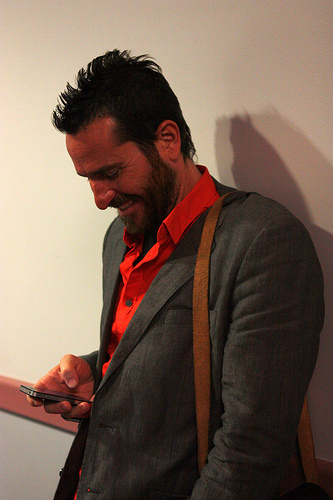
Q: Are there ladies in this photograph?
A: No, there are no ladies.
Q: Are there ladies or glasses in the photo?
A: No, there are no ladies or glasses.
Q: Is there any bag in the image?
A: Yes, there is a bag.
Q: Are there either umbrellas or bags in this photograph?
A: Yes, there is a bag.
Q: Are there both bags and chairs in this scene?
A: No, there is a bag but no chairs.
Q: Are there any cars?
A: No, there are no cars.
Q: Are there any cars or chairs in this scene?
A: No, there are no cars or chairs.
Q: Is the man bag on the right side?
A: Yes, the bag is on the right of the image.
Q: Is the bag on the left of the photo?
A: No, the bag is on the right of the image.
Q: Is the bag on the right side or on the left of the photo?
A: The bag is on the right of the image.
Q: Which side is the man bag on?
A: The bag is on the right of the image.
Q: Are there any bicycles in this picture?
A: No, there are no bicycles.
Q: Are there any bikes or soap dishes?
A: No, there are no bikes or soap dishes.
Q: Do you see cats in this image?
A: No, there are no cats.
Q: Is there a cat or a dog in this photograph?
A: No, there are no cats or dogs.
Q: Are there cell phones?
A: Yes, there is a cell phone.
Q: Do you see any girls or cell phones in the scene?
A: Yes, there is a cell phone.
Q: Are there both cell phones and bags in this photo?
A: Yes, there are both a cell phone and a bag.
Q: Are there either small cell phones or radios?
A: Yes, there is a small cell phone.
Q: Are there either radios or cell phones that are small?
A: Yes, the cell phone is small.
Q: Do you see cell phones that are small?
A: Yes, there is a small cell phone.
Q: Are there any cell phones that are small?
A: Yes, there is a cell phone that is small.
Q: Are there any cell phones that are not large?
A: Yes, there is a small cell phone.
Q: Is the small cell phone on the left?
A: Yes, the mobile phone is on the left of the image.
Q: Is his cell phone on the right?
A: No, the mobile phone is on the left of the image.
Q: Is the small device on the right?
A: No, the mobile phone is on the left of the image.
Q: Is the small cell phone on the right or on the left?
A: The mobile phone is on the left of the image.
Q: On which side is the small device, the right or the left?
A: The mobile phone is on the left of the image.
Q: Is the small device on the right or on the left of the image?
A: The mobile phone is on the left of the image.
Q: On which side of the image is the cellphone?
A: The cellphone is on the left of the image.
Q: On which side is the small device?
A: The cellphone is on the left of the image.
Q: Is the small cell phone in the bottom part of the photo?
A: Yes, the cellphone is in the bottom of the image.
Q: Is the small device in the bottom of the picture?
A: Yes, the cellphone is in the bottom of the image.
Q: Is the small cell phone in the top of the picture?
A: No, the cell phone is in the bottom of the image.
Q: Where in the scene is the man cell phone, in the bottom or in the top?
A: The cellphone is in the bottom of the image.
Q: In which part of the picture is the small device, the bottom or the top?
A: The cellphone is in the bottom of the image.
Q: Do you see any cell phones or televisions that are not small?
A: No, there is a cell phone but it is small.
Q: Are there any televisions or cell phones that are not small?
A: No, there is a cell phone but it is small.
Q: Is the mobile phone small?
A: Yes, the mobile phone is small.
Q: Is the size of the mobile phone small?
A: Yes, the mobile phone is small.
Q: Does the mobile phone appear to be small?
A: Yes, the mobile phone is small.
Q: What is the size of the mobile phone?
A: The mobile phone is small.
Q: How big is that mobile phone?
A: The mobile phone is small.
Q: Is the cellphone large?
A: No, the cellphone is small.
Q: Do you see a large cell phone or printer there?
A: No, there is a cell phone but it is small.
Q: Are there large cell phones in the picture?
A: No, there is a cell phone but it is small.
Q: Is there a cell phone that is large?
A: No, there is a cell phone but it is small.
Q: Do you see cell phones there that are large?
A: No, there is a cell phone but it is small.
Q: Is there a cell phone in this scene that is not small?
A: No, there is a cell phone but it is small.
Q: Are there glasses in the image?
A: No, there are no glasses.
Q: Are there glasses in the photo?
A: No, there are no glasses.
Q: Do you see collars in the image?
A: Yes, there is a collar.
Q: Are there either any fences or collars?
A: Yes, there is a collar.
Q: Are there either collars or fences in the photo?
A: Yes, there is a collar.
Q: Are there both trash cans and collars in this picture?
A: No, there is a collar but no trash cans.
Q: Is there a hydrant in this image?
A: No, there are no fire hydrants.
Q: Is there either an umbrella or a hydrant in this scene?
A: No, there are no fire hydrants or umbrellas.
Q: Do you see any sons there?
A: No, there are no sons.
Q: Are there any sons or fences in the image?
A: No, there are no sons or fences.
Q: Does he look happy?
A: Yes, the man is happy.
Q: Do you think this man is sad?
A: No, the man is happy.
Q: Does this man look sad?
A: No, the man is happy.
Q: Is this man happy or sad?
A: The man is happy.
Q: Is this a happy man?
A: Yes, this is a happy man.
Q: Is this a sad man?
A: No, this is a happy man.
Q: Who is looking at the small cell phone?
A: The man is looking at the mobile phone.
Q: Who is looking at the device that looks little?
A: The man is looking at the mobile phone.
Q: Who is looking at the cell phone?
A: The man is looking at the mobile phone.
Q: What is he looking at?
A: The man is looking at the cell phone.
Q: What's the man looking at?
A: The man is looking at the cell phone.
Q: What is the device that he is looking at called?
A: The device is a cell phone.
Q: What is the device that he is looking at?
A: The device is a cell phone.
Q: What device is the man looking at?
A: The man is looking at the cellphone.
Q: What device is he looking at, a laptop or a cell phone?
A: The man is looking at a cell phone.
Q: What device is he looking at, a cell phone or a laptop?
A: The man is looking at a cell phone.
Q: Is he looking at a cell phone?
A: Yes, the man is looking at a cell phone.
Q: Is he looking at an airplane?
A: No, the man is looking at a cell phone.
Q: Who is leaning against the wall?
A: The man is leaning against the wall.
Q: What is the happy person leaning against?
A: The man is leaning against the wall.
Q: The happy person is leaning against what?
A: The man is leaning against the wall.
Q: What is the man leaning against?
A: The man is leaning against the wall.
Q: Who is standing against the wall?
A: The man is standing against the wall.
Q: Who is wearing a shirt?
A: The man is wearing a shirt.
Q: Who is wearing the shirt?
A: The man is wearing a shirt.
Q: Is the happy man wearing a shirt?
A: Yes, the man is wearing a shirt.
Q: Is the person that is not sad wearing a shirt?
A: Yes, the man is wearing a shirt.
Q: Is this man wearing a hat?
A: No, the man is wearing a shirt.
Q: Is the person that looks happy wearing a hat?
A: No, the man is wearing a shirt.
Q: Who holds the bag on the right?
A: The man holds the bag.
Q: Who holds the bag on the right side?
A: The man holds the bag.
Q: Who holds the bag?
A: The man holds the bag.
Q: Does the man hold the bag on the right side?
A: Yes, the man holds the bag.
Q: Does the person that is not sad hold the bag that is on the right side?
A: Yes, the man holds the bag.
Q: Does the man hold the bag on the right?
A: Yes, the man holds the bag.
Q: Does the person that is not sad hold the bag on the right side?
A: Yes, the man holds the bag.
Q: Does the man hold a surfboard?
A: No, the man holds the bag.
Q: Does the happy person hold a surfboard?
A: No, the man holds the bag.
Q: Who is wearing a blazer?
A: The man is wearing a blazer.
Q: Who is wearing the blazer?
A: The man is wearing a blazer.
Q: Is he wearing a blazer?
A: Yes, the man is wearing a blazer.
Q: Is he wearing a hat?
A: No, the man is wearing a blazer.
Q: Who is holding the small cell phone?
A: The man is holding the mobile phone.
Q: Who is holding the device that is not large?
A: The man is holding the mobile phone.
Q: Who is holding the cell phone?
A: The man is holding the mobile phone.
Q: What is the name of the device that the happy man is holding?
A: The device is a cell phone.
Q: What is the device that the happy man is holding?
A: The device is a cell phone.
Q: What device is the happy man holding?
A: The man is holding the cellphone.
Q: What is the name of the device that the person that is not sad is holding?
A: The device is a cell phone.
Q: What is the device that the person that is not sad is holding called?
A: The device is a cell phone.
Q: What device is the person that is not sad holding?
A: The man is holding the cellphone.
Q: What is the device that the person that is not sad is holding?
A: The device is a cell phone.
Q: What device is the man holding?
A: The man is holding the cellphone.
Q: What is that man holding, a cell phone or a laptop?
A: The man is holding a cell phone.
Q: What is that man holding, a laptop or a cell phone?
A: The man is holding a cell phone.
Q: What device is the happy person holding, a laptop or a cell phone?
A: The man is holding a cell phone.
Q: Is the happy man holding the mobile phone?
A: Yes, the man is holding the mobile phone.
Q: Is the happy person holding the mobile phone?
A: Yes, the man is holding the mobile phone.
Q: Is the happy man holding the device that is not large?
A: Yes, the man is holding the mobile phone.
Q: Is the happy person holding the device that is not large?
A: Yes, the man is holding the mobile phone.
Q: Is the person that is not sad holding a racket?
A: No, the man is holding the mobile phone.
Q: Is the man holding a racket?
A: No, the man is holding the mobile phone.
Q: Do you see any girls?
A: No, there are no girls.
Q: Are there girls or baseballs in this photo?
A: No, there are no girls or baseballs.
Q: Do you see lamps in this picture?
A: No, there are no lamps.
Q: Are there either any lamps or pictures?
A: No, there are no lamps or pictures.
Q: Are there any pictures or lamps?
A: No, there are no lamps or pictures.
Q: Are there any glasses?
A: No, there are no glasses.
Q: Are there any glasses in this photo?
A: No, there are no glasses.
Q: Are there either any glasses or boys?
A: No, there are no glasses or boys.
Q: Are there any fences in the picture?
A: No, there are no fences.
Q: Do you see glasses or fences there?
A: No, there are no fences or glasses.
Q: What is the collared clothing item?
A: The clothing item is a shirt.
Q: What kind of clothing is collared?
A: The clothing is a shirt.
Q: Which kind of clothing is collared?
A: The clothing is a shirt.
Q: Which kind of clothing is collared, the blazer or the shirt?
A: The shirt is collared.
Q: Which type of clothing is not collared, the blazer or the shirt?
A: The blazer is not collared.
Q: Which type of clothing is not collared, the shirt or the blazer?
A: The blazer is not collared.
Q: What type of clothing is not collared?
A: The clothing is a blazer.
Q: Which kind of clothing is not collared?
A: The clothing is a blazer.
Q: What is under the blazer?
A: The shirt is under the blazer.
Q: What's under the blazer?
A: The shirt is under the blazer.